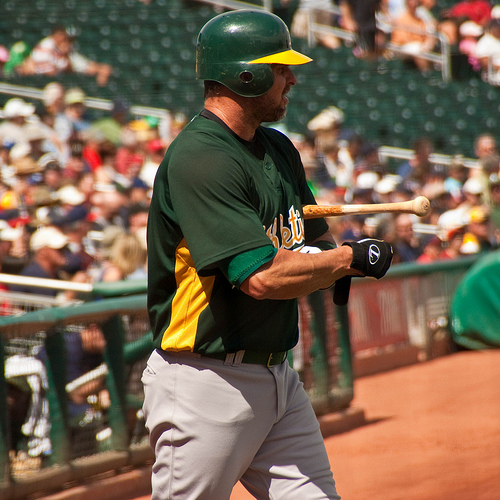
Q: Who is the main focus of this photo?
A: Ballplayer.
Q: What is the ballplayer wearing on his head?
A: Helmet.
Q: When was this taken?
A: Daytime.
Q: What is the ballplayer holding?
A: Bat.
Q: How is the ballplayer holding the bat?
A: Under left arm.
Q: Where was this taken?
A: Ball field.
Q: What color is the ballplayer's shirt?
A: Green and yellow.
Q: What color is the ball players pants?
A: White.